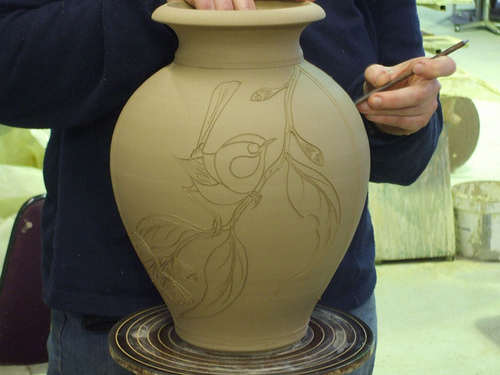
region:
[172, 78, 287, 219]
bird etched into pot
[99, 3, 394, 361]
large ceramic pot on wheel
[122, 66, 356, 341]
bird on tree branch artwork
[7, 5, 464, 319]
dark blue long sleeved shirt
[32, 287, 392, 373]
blue denim men's jeans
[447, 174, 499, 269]
gray and white plastic pail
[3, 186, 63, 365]
back of vinyl chair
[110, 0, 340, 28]
fingers gripping top of clay pot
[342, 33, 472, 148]
hand holding etching tool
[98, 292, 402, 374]
dirty pottery wheel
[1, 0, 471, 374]
person making a vase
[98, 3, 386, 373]
tan ceramic vase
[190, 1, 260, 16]
hand inside the vase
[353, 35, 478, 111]
writing utensil in the hand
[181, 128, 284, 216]
drawing of a bird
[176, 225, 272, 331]
long leaf hanging off the branch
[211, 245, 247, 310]
veins in the leaf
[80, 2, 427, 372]
vase on a pedestal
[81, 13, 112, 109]
wrinkle in the leaf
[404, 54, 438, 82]
index finger resting on the writing utensil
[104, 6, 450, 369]
a vase on a table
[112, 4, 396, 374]
a ceramin vase on a table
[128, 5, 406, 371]
a pottery vase on a table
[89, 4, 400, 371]
a vase in the making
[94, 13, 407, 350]
a wet vase in the making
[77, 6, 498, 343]
a man designing the vase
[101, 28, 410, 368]
a bird on a vase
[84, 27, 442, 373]
a bird standing on a branch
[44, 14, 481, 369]
a bird etched into the vase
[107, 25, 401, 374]
a vase on a turntable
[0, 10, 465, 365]
potter working on a new vase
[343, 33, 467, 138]
potter's hand making designs in a vase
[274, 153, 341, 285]
leaf etched into a vase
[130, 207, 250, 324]
leaves etched into a vase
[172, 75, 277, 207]
bird etched into a vase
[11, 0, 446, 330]
potter wearing a long sleeve blue shirt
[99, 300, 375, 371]
potter's wheel with vase sitting on it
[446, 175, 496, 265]
dirty bucket in the background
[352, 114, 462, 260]
part of a leaning wooden table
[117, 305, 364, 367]
rings on top of a potter's wheel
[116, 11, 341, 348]
A flower pot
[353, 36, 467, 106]
A pen in the hand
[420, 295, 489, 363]
A concrete floor.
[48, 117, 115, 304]
A blue sweater in the photo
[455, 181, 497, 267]
A white bucket in the background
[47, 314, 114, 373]
Blue jeans in the photo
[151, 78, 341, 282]
A flower art on the pot.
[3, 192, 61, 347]
A chair in the background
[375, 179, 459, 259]
A wooden log in the background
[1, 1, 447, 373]
A person standing in the photo